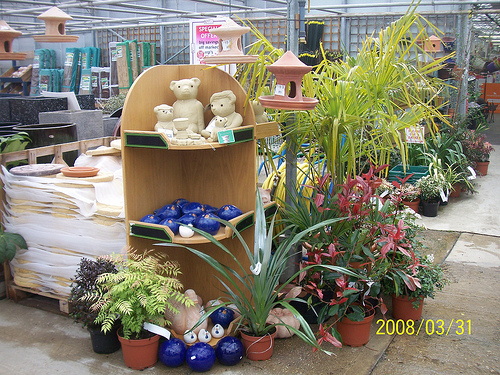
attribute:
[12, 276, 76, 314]
pallet — wooden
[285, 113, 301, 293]
pole — metal, structure, support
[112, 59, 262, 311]
display shelf — wooden 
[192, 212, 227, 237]
pottery — blue, decorative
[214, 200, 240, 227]
pottery — blue, decorative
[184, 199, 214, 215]
pottery — blue, decorative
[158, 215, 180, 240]
pottery — blue, decorative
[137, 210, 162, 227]
pottery — blue, decorative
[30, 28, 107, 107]
feeder — bird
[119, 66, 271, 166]
bears — decorative, ceramic, for sale